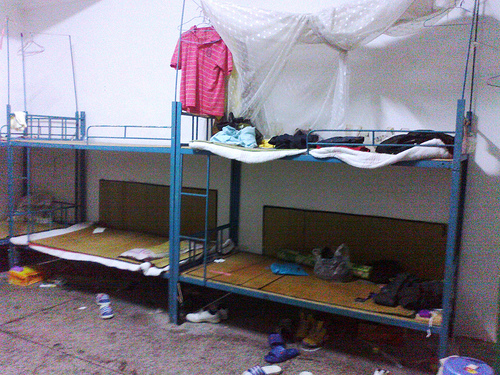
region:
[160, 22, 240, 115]
pink shirt on clothes hanger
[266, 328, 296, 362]
blue sandals on floor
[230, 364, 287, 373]
white and blue sandals on floor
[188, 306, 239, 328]
white tennis shoes on floor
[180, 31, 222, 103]
pink shirt with white stripes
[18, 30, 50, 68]
clothes hanger with no clothes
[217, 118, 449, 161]
piles of clothes laying on bed frame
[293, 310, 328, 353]
shoes with yellow on top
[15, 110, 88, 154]
blue frame to bed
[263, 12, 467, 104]
white canopy sheet around bed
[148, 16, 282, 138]
this is a shirt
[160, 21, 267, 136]
this shirt has stripes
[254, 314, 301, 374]
this is a pair of shoes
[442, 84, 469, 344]
this is a blue pole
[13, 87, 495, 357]
this is a set of beds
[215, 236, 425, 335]
a brown mat on the bed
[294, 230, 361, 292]
plastic bag on the bed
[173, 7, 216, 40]
this is coat hanger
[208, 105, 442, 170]
different piles of clothes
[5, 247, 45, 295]
orange box on floor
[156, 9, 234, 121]
red shirt on hanger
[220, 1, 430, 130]
white sheet over bed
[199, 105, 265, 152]
blue shirt on bed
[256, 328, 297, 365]
blue shoes on floor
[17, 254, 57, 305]
orange box on floor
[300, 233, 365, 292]
purse on lower bunk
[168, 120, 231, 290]
blue ladder on bed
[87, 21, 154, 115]
white wall behind bed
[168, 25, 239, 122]
PINK SHIRT ON HANGER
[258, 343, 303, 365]
BLUE SLIP ON SHOE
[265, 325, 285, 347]
BLUE SLIP ON SHOE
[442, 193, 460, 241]
PART OF BLUE SHELVING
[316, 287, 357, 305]
PANEL FOR SHELF BOTTOM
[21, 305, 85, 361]
PART OF STORAGE FLOOR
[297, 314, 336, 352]
PART OF BROWN WORK BOOT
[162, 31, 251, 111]
red shirt on hanger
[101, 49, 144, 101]
white wall behind bed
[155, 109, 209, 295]
blue ladder on bunk bed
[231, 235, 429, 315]
brown slat on bunk bed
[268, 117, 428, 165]
clothes on top bunk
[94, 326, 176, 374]
floor is dark grey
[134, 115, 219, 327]
blue posts on bed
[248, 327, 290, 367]
shoes are dark blue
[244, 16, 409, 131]
white sheet over bed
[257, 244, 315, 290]
light blue shirt on bottom bunk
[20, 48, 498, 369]
a group of beds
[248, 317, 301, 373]
a pair of shoes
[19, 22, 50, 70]
coat hanger on the side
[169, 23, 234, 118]
striped pink polo shirt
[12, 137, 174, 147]
bare top left bunk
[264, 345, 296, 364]
dark blue left plastic sandal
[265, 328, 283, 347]
dark blue right plastic sandal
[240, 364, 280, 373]
white and blue right plastic sandal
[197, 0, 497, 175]
sheer white fabric hanging above bunk beds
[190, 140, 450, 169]
white blanket hanging over side of top right bed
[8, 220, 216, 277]
white blanket hanging over side of bottom left bed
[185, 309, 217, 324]
right white tennis shoe underneath bed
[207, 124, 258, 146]
light blue clothing on top right bunk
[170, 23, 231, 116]
Pink and white striped shirt on a hanger.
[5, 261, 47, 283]
Yellow and orange bag on the floor.